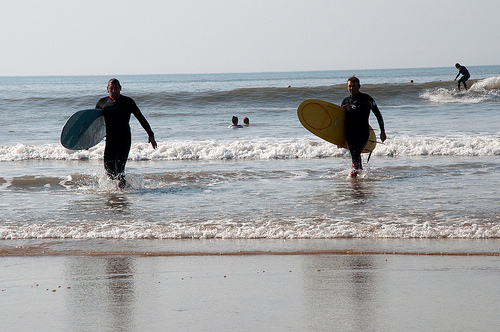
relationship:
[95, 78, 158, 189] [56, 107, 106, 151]
person carrying board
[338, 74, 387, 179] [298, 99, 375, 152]
man carrying surfboard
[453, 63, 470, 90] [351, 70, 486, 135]
surfer riding wave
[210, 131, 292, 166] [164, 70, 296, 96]
wave in ocean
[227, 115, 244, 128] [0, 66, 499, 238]
people heads out of ocean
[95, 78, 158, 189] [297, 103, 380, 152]
person holding surfboards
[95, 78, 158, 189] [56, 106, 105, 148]
person holding surfboards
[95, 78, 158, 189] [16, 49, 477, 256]
person on shore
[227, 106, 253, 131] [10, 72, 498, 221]
people swimming in ocean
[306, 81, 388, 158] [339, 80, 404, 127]
man in wetsuit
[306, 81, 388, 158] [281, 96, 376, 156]
man holding surfboard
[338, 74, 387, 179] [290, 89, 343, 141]
man holding surfboard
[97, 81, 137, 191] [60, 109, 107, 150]
person holding board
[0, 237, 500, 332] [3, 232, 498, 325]
beach on beach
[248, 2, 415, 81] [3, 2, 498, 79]
sky above ocean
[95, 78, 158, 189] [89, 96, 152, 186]
person wearing wetsuit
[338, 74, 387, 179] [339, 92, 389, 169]
man wearing wetsuit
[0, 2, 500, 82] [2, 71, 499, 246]
sky above ocean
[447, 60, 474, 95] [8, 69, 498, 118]
surfer on wave